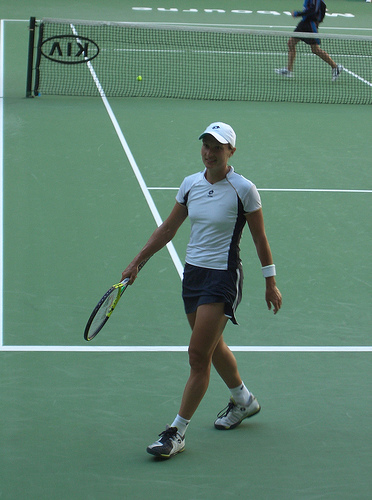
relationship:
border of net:
[41, 17, 371, 44] [35, 15, 370, 110]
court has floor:
[0, 0, 367, 499] [3, 2, 369, 497]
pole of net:
[24, 16, 34, 97] [35, 15, 370, 110]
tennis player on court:
[269, 1, 343, 87] [0, 0, 372, 500]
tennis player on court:
[119, 115, 284, 464] [0, 0, 372, 500]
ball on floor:
[137, 74, 142, 79] [14, 80, 259, 121]